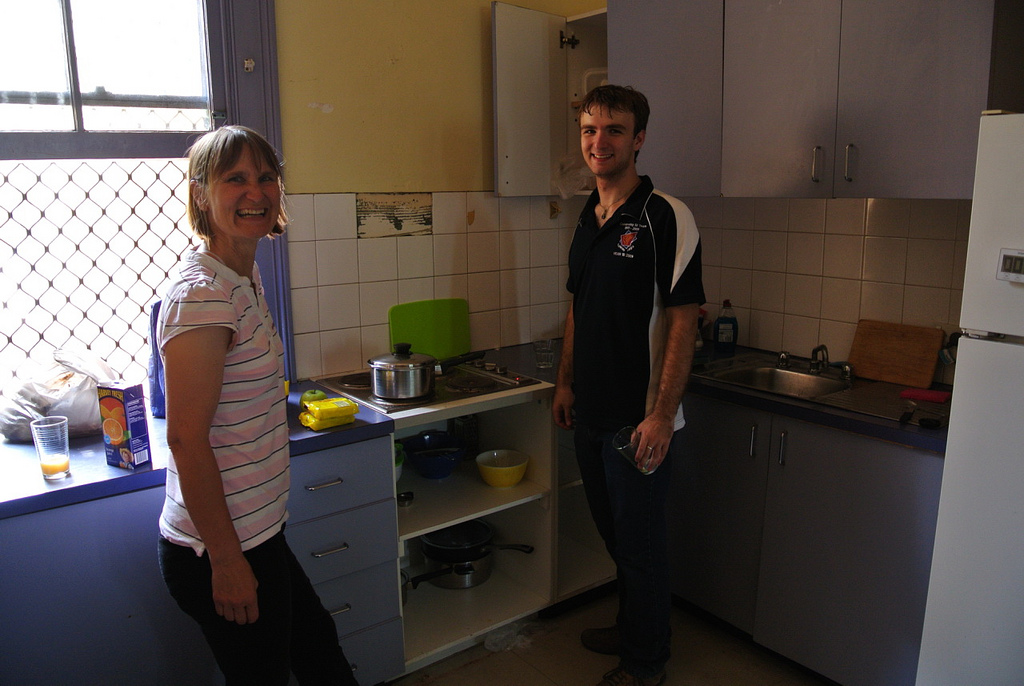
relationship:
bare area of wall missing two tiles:
[348, 176, 446, 263] [337, 243, 390, 293]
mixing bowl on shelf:
[449, 421, 534, 519] [408, 485, 465, 633]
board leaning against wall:
[848, 318, 944, 388] [970, 319, 992, 372]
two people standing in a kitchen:
[149, 112, 785, 683] [32, 207, 1003, 686]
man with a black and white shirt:
[555, 83, 698, 686] [588, 274, 664, 406]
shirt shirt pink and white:
[139, 258, 293, 544] [166, 540, 223, 601]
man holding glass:
[555, 83, 698, 686] [616, 385, 669, 481]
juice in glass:
[39, 455, 69, 475] [27, 410, 73, 486]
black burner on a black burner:
[365, 342, 497, 399] [319, 361, 507, 411]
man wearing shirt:
[544, 80, 704, 670] [563, 173, 710, 437]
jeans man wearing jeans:
[584, 414, 690, 685] [633, 483, 694, 644]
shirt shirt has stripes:
[139, 258, 293, 544] [225, 377, 260, 566]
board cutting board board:
[388, 298, 470, 359] [388, 298, 470, 359]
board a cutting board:
[388, 298, 470, 359] [410, 313, 454, 361]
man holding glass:
[544, 80, 704, 670] [608, 432, 661, 476]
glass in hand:
[608, 432, 661, 476] [634, 409, 674, 466]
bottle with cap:
[706, 294, 745, 359] [716, 294, 736, 308]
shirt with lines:
[139, 258, 293, 544] [228, 320, 278, 373]